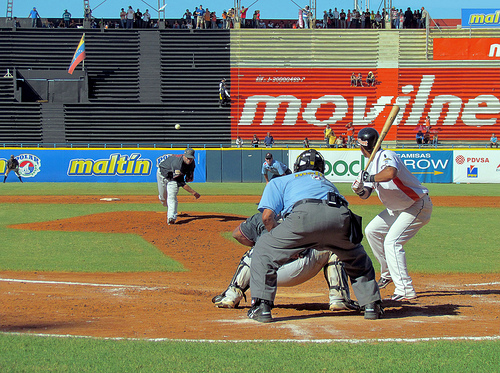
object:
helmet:
[358, 125, 385, 150]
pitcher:
[154, 145, 199, 225]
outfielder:
[2, 154, 23, 183]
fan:
[365, 68, 379, 88]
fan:
[354, 72, 364, 85]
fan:
[348, 73, 357, 86]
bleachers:
[5, 10, 483, 175]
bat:
[364, 105, 401, 170]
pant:
[245, 202, 381, 307]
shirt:
[239, 7, 249, 20]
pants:
[364, 193, 433, 299]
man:
[351, 99, 434, 311]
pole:
[79, 34, 87, 72]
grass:
[46, 230, 152, 268]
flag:
[68, 34, 87, 74]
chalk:
[285, 321, 312, 342]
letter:
[237, 89, 299, 127]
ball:
[174, 121, 182, 131]